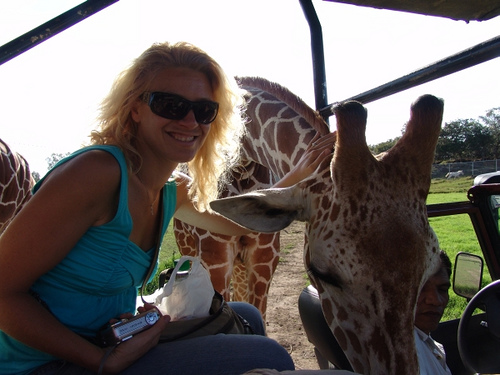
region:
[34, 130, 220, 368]
woman's shirt is blue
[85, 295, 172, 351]
camera is silver and pink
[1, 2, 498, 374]
Woman is sitting in vehicle.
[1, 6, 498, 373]
Vehicles sides are open.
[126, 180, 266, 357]
Woman has a shoulder bag.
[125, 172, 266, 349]
Shoulder bag is in woman's lap.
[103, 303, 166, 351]
Woman is holding a camera.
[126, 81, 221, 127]
Woman is wearing dark sunglasses.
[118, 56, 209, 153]
The woman is smiling.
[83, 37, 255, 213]
Woman has blonde hair.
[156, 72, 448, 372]
Woman is petting giraffe.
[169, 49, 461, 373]
The giraffe is very friendly.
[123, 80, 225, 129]
Woman is wearing sunglasses.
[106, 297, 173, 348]
Woman is holding camera.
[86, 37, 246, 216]
The woman is smiling.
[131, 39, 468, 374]
Giraffe's head is in vehicle.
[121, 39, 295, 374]
Giraffe's body is outside vehicle.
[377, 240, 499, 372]
Man is sitting behind steering wheel.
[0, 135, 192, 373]
Woman is wearing blue shirt.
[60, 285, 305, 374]
Woman is wearing blue jeans.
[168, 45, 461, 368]
Giraffe is brown and tan.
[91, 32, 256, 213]
The woman has hair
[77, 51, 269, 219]
The woman has blond hair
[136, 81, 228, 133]
The woman is wearing sunglasses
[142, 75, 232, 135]
The woman is wearing black sunglasses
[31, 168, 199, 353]
The woman is wearing a shirt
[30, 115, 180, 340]
The woman is wearing a blue shirt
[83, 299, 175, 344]
The woman has a camera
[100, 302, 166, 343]
The woman has a grey shirt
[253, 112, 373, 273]
The giraffe is brown and white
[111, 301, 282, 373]
The woman is wearing pants